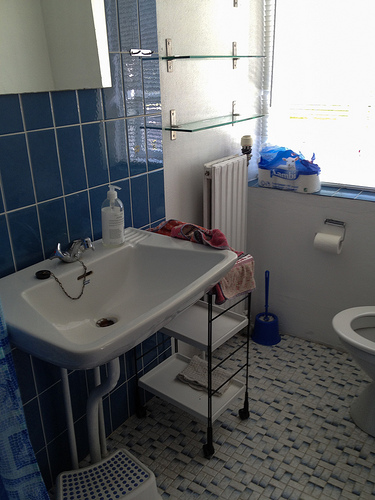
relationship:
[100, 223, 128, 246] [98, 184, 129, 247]
soap in bottle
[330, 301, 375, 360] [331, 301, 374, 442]
seat on toilet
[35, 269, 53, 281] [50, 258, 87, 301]
stopper on chain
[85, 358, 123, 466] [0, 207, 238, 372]
pipes to sink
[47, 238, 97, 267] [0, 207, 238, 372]
faucet on sink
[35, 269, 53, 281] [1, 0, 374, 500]
plug in bathroom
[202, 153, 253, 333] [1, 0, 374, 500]
radiator in bathroom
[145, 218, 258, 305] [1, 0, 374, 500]
towels in bathroom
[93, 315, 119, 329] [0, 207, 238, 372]
hole in sink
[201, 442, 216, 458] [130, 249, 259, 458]
wheel on holder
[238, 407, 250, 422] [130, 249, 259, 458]
wheel on holder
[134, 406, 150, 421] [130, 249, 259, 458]
wheel on holder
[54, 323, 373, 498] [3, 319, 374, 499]
tiles on floor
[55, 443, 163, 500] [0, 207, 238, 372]
stool underneath sink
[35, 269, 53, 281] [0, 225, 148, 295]
plug on ledge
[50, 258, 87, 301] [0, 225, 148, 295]
chain on ledge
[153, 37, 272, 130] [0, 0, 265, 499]
racks on wall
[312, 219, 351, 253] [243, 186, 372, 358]
holder on wall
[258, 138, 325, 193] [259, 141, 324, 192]
paper in packaging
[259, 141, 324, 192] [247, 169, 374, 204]
packaging on sill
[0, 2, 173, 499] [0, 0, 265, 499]
tiles on wall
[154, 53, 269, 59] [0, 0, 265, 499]
shelf on wall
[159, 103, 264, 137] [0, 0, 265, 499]
racks on wall